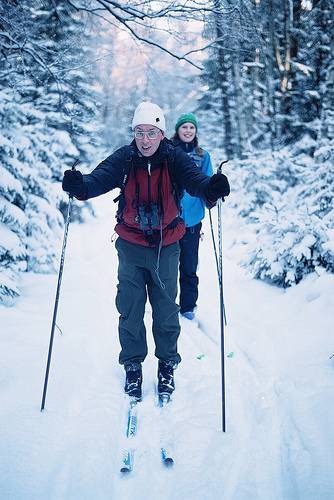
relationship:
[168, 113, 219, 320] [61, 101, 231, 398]
woman behind a skier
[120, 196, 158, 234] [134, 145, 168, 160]
binoculars on neck